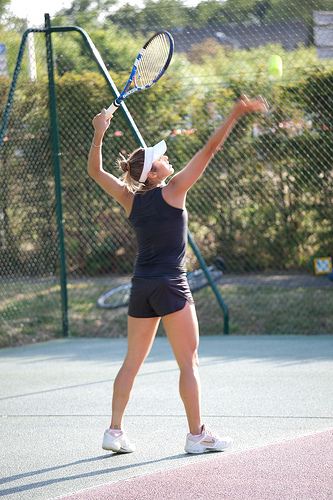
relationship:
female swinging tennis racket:
[85, 100, 272, 460] [100, 25, 172, 116]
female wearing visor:
[85, 100, 272, 460] [136, 143, 170, 185]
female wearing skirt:
[85, 100, 272, 460] [126, 270, 188, 319]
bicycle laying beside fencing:
[100, 258, 226, 302] [4, 2, 331, 335]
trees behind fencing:
[3, 4, 332, 280] [4, 2, 331, 335]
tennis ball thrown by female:
[266, 54, 287, 81] [85, 100, 272, 460]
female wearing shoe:
[85, 100, 272, 460] [187, 423, 234, 451]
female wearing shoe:
[85, 100, 272, 460] [98, 423, 136, 457]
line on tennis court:
[43, 412, 331, 493] [5, 332, 331, 499]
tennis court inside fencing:
[5, 332, 331, 499] [4, 2, 331, 335]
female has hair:
[85, 100, 272, 460] [119, 144, 159, 190]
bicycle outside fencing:
[100, 258, 226, 302] [4, 2, 331, 335]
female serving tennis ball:
[85, 100, 272, 460] [266, 54, 287, 81]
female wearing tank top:
[85, 100, 272, 460] [125, 192, 190, 272]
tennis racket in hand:
[100, 25, 172, 116] [88, 110, 117, 136]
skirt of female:
[126, 270, 188, 319] [85, 100, 272, 460]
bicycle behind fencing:
[100, 258, 226, 302] [4, 2, 331, 335]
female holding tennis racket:
[85, 100, 272, 460] [100, 25, 172, 116]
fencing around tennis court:
[4, 2, 331, 335] [5, 332, 331, 499]